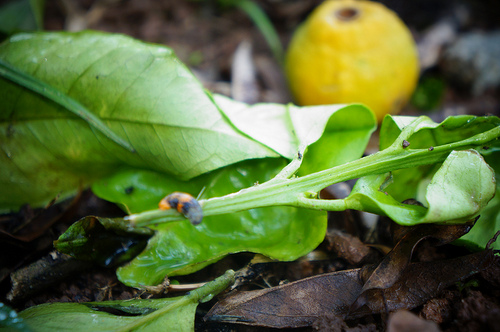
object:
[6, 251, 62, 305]
stem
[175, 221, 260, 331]
ground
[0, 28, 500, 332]
leaves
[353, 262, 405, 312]
ground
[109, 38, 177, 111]
veins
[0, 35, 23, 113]
leaf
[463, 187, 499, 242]
leaf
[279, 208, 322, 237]
leaf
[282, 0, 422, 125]
lemon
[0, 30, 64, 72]
veins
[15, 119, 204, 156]
veins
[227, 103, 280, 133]
leaf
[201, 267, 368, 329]
dead leaf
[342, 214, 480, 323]
dead leaf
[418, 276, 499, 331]
ground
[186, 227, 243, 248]
leaf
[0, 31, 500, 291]
green leaves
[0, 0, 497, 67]
ground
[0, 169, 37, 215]
leaf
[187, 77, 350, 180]
reflection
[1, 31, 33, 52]
leaf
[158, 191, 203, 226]
insect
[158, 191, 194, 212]
stripes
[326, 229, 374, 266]
bark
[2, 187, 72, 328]
ground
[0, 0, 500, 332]
plant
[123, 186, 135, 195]
bug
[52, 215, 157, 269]
stem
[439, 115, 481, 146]
leaf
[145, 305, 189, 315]
leaf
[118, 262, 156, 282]
leaf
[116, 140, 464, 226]
stem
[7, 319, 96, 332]
leaf